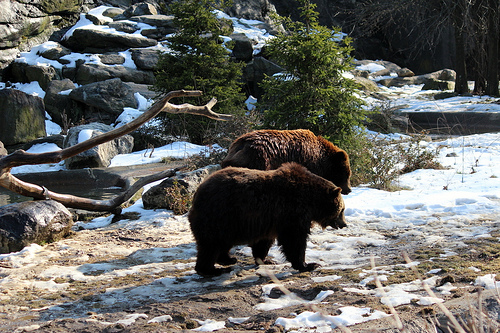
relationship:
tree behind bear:
[257, 2, 371, 184] [218, 126, 353, 195]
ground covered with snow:
[1, 130, 499, 330] [18, 136, 497, 279]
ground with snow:
[1, 149, 498, 331] [308, 129, 498, 273]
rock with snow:
[2, 50, 59, 88] [6, 51, 147, 87]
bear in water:
[187, 163, 348, 278] [393, 100, 491, 137]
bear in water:
[218, 126, 353, 195] [393, 100, 491, 137]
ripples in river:
[313, 217, 373, 259] [359, 193, 473, 250]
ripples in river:
[79, 183, 98, 200] [0, 107, 492, 224]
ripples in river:
[438, 113, 465, 123] [375, 100, 496, 155]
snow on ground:
[275, 296, 372, 331] [1, 149, 498, 331]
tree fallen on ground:
[1, 89, 230, 169] [1, 130, 499, 330]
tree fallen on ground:
[12, 170, 182, 215] [1, 130, 499, 330]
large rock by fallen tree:
[5, 199, 75, 247] [4, 32, 423, 212]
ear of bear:
[329, 184, 344, 203] [187, 163, 348, 278]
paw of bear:
[295, 260, 320, 273] [187, 163, 348, 278]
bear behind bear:
[218, 126, 353, 195] [187, 163, 348, 278]